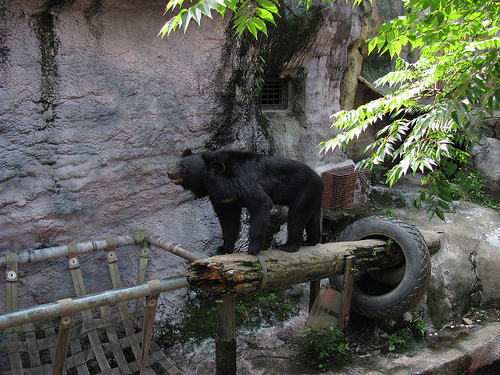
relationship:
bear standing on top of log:
[164, 145, 326, 255] [184, 226, 441, 305]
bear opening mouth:
[164, 145, 326, 255] [168, 173, 186, 184]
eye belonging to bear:
[175, 160, 188, 171] [164, 145, 326, 255]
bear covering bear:
[163, 145, 325, 255] [164, 145, 326, 255]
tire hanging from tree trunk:
[328, 215, 432, 325] [183, 227, 441, 305]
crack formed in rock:
[465, 240, 485, 310] [366, 185, 484, 341]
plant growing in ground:
[263, 290, 275, 308] [1, 107, 483, 372]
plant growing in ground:
[236, 300, 249, 318] [1, 107, 483, 372]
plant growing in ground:
[198, 302, 218, 321] [1, 107, 483, 372]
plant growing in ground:
[243, 291, 259, 302] [1, 107, 483, 372]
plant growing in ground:
[199, 320, 218, 335] [1, 107, 483, 372]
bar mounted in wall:
[260, 96, 282, 100] [1, 1, 484, 332]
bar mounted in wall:
[258, 90, 280, 96] [1, 1, 484, 332]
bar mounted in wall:
[260, 84, 282, 90] [1, 1, 484, 332]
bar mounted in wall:
[263, 78, 269, 105] [1, 1, 484, 332]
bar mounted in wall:
[270, 75, 274, 102] [1, 1, 484, 332]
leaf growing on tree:
[407, 158, 420, 176] [153, 0, 483, 222]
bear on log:
[163, 145, 325, 255] [184, 231, 391, 310]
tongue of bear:
[167, 171, 181, 184] [171, 144, 323, 246]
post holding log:
[212, 305, 243, 372] [189, 239, 402, 320]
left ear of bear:
[176, 147, 192, 157] [171, 144, 323, 246]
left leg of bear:
[209, 207, 241, 250] [171, 144, 323, 246]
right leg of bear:
[242, 204, 279, 253] [165, 151, 319, 246]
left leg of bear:
[309, 190, 331, 247] [174, 160, 318, 250]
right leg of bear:
[287, 201, 306, 254] [164, 145, 326, 255]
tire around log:
[328, 215, 432, 325] [184, 231, 391, 310]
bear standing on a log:
[163, 145, 325, 255] [192, 244, 396, 307]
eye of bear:
[175, 160, 188, 171] [163, 145, 325, 255]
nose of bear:
[165, 166, 180, 178] [163, 145, 325, 255]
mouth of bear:
[170, 179, 180, 187] [163, 145, 325, 255]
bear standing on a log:
[163, 145, 325, 255] [189, 237, 399, 313]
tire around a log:
[328, 215, 432, 325] [184, 231, 394, 303]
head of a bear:
[167, 146, 205, 200] [163, 145, 325, 255]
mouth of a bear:
[170, 179, 180, 187] [163, 145, 325, 255]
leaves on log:
[252, 253, 271, 280] [192, 233, 385, 323]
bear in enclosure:
[163, 145, 325, 255] [4, 2, 498, 372]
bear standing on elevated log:
[163, 145, 325, 255] [184, 242, 391, 303]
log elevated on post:
[193, 231, 389, 299] [208, 297, 236, 373]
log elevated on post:
[193, 231, 389, 299] [329, 271, 374, 372]